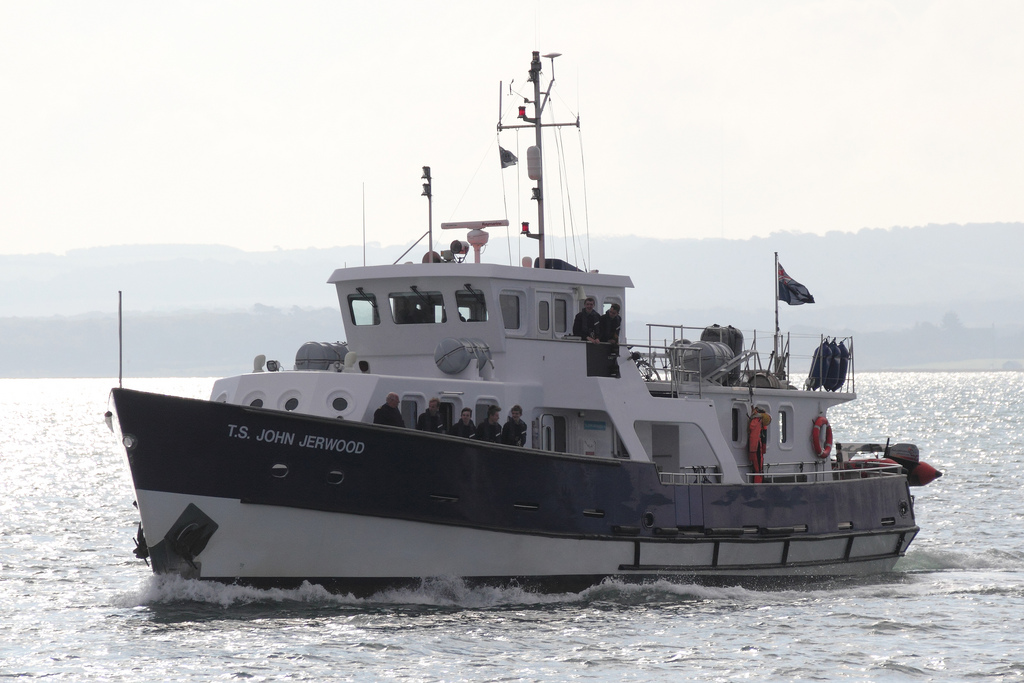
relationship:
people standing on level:
[555, 284, 651, 393] [255, 250, 874, 393]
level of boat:
[255, 250, 874, 393] [92, 53, 946, 618]